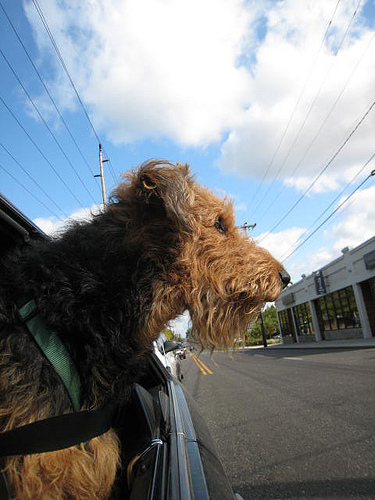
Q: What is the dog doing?
A: Looking out of a car window.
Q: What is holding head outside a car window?
A: A dog.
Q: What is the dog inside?
A: Black car with window down.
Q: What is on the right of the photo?
A: Storefronts with large glass windows.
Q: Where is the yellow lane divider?
A: On the paved street.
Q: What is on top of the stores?
A: Multiple telephone and power lines.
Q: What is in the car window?
A: Dog with canvas restraints.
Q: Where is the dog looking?
A: Out the window.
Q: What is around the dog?
A: Seat belt.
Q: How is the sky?
A: Cloudy.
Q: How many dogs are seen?
A: One.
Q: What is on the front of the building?
A: Windows.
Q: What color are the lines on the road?
A: Yellow.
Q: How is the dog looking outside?
A: Through the window.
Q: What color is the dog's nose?
A: Black.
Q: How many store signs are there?
A: 3.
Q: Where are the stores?
A: On right.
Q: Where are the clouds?
A: The sky.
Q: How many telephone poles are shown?
A: 2.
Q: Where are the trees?
A: Background.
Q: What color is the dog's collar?
A: Green.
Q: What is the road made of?
A: Tar.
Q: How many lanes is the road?
A: 2.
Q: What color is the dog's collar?
A: Green.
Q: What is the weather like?
A: Blue skies with clouds.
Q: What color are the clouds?
A: White and gray.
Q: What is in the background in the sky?
A: Electrical wires.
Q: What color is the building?
A: White.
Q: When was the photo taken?
A: During the day.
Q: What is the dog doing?
A: Sticking his head out the window.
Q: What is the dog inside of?
A: A car.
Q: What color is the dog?
A: Brown.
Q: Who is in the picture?
A: No one.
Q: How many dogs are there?
A: One.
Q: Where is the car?
A: In the street.